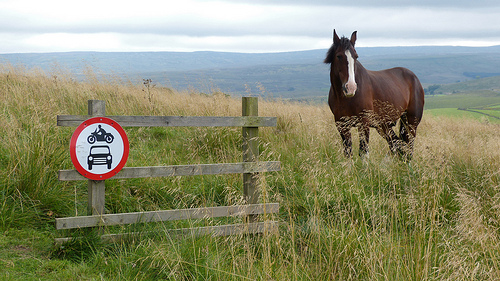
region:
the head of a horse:
[319, 25, 364, 103]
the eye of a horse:
[333, 50, 346, 61]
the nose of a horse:
[341, 80, 359, 95]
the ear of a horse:
[346, 26, 361, 47]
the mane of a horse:
[321, 32, 354, 67]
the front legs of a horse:
[333, 121, 376, 171]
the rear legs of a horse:
[373, 116, 425, 161]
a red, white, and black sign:
[66, 113, 132, 183]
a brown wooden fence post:
[236, 90, 268, 248]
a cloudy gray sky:
[0, 0, 499, 57]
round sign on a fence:
[60, 112, 133, 194]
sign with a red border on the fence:
[64, 117, 140, 190]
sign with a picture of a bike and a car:
[70, 116, 132, 188]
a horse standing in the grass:
[318, 32, 450, 174]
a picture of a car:
[78, 145, 119, 172]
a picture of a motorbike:
[86, 125, 117, 146]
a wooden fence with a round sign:
[50, 93, 327, 253]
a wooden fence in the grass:
[45, 91, 319, 266]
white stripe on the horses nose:
[334, 47, 364, 110]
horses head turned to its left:
[322, 29, 367, 115]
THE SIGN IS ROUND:
[60, 110, 145, 193]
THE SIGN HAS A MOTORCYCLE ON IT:
[83, 121, 114, 146]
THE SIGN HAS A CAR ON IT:
[83, 143, 121, 174]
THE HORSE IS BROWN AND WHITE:
[313, 27, 445, 170]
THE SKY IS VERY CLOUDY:
[1, 1, 499, 71]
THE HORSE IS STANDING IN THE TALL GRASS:
[316, 20, 428, 184]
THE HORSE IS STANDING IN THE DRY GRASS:
[315, 27, 431, 164]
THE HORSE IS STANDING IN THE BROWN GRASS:
[317, 18, 432, 165]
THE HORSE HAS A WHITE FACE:
[333, 45, 358, 110]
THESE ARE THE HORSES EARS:
[328, 25, 359, 52]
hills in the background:
[15, 52, 290, 79]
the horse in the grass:
[296, 20, 471, 175]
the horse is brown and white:
[305, 15, 471, 190]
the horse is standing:
[310, 26, 440, 156]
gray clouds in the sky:
[16, 10, 263, 33]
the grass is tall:
[291, 122, 486, 276]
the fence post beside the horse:
[48, 79, 291, 253]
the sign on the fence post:
[49, 108, 144, 185]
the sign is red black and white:
[59, 108, 133, 184]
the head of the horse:
[315, 19, 377, 110]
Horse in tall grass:
[314, 22, 456, 179]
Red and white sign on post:
[55, 110, 170, 197]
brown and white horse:
[301, 15, 451, 166]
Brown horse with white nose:
[321, 25, 383, 110]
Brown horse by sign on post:
[265, 26, 467, 164]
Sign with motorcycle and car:
[58, 108, 155, 188]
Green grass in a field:
[245, 125, 465, 249]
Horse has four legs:
[312, 97, 445, 170]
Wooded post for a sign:
[143, 121, 309, 251]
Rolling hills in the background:
[148, 37, 323, 137]